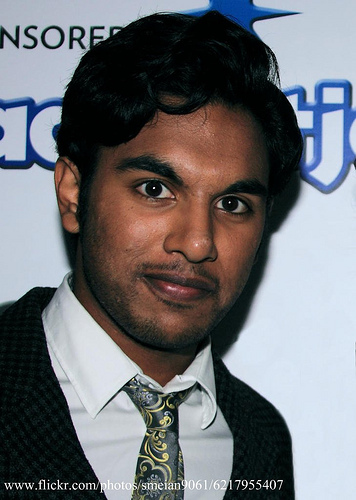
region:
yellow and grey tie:
[94, 350, 315, 489]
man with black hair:
[31, 22, 269, 304]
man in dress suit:
[17, 50, 321, 487]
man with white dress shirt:
[17, 257, 227, 499]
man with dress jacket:
[7, 262, 251, 482]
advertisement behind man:
[9, 31, 336, 213]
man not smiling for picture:
[113, 120, 241, 436]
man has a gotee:
[81, 200, 266, 403]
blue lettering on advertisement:
[18, 70, 348, 269]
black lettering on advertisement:
[5, 4, 157, 75]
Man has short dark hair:
[42, 2, 344, 195]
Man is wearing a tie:
[110, 379, 213, 499]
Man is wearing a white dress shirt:
[33, 292, 236, 498]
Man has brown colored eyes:
[125, 156, 259, 229]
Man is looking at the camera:
[54, 53, 302, 368]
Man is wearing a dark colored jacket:
[20, 337, 312, 498]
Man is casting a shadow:
[197, 173, 318, 361]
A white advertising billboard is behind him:
[1, 22, 355, 194]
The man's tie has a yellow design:
[116, 375, 198, 499]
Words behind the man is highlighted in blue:
[0, 67, 354, 202]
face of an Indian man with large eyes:
[22, 15, 338, 387]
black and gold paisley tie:
[112, 369, 210, 495]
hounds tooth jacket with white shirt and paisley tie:
[7, 288, 166, 487]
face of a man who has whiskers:
[28, 100, 354, 317]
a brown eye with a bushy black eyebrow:
[114, 151, 184, 222]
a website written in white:
[2, 473, 285, 495]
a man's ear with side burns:
[39, 151, 117, 267]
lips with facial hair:
[130, 255, 239, 316]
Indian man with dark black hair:
[32, 9, 336, 353]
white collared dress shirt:
[39, 284, 137, 412]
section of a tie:
[160, 441, 176, 457]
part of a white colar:
[79, 336, 113, 376]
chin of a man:
[160, 331, 176, 336]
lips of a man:
[173, 284, 204, 293]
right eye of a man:
[146, 175, 168, 200]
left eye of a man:
[223, 191, 249, 216]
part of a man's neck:
[158, 356, 175, 367]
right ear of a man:
[60, 174, 75, 210]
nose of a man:
[191, 229, 207, 253]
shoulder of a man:
[248, 400, 274, 411]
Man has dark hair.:
[99, 32, 204, 150]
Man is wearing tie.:
[114, 391, 186, 484]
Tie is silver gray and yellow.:
[140, 377, 205, 494]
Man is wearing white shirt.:
[67, 364, 227, 496]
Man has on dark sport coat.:
[19, 341, 89, 498]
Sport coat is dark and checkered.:
[25, 358, 81, 472]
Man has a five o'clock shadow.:
[101, 253, 243, 381]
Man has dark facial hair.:
[88, 278, 222, 360]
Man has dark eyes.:
[138, 168, 289, 231]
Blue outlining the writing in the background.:
[6, 75, 341, 185]